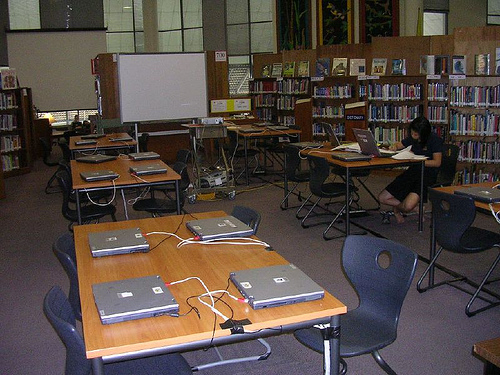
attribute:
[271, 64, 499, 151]
shelves — for book, in rows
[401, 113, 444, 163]
person — studying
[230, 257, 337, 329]
laptop — gray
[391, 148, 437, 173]
ground — white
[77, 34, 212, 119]
board — white, dry erase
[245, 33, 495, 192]
cases — slanted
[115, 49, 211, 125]
board — dry erase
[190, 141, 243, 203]
wires — various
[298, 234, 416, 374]
chair — plastic, gray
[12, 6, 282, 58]
windows — covered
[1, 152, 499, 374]
carpet — gray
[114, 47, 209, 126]
panel — blank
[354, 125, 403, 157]
laptop — open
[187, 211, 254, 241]
laptop — closed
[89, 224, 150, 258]
laptop — closed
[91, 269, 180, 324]
laptop — closed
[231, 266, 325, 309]
laptop — closed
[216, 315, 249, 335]
tape — black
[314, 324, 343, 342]
tape — black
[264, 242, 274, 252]
tape — black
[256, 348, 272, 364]
tape — black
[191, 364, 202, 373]
tape — black